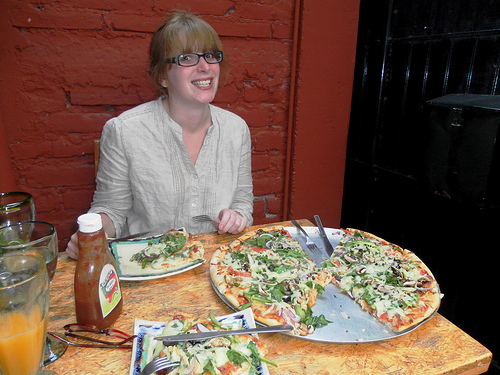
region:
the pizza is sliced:
[217, 227, 429, 369]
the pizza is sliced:
[233, 184, 350, 345]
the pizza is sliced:
[303, 224, 400, 372]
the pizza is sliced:
[266, 207, 383, 344]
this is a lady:
[123, 2, 242, 229]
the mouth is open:
[191, 73, 217, 88]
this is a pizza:
[342, 241, 404, 293]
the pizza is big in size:
[357, 245, 408, 295]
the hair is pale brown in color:
[164, 15, 208, 49]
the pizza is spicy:
[348, 252, 403, 307]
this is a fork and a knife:
[302, 217, 329, 245]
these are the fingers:
[221, 205, 243, 230]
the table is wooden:
[398, 315, 465, 370]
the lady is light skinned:
[186, 100, 206, 124]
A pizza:
[354, 276, 379, 308]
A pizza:
[336, 282, 382, 332]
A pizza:
[246, 214, 284, 293]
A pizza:
[254, 234, 292, 290]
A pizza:
[247, 271, 316, 366]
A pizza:
[199, 189, 299, 374]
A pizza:
[184, 241, 245, 316]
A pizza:
[191, 217, 270, 327]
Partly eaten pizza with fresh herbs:
[211, 213, 444, 347]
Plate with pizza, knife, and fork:
[133, 310, 261, 372]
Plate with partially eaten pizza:
[111, 227, 203, 282]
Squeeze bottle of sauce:
[76, 212, 131, 333]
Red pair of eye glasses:
[43, 321, 136, 350]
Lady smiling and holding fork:
[126, 20, 256, 235]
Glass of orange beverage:
[0, 253, 60, 370]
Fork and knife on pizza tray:
[283, 211, 339, 262]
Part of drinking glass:
[0, 182, 35, 242]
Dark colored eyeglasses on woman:
[157, 48, 227, 70]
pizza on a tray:
[214, 176, 426, 336]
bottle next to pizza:
[78, 218, 136, 353]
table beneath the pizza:
[412, 342, 444, 365]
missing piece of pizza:
[324, 298, 360, 345]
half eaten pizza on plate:
[130, 224, 205, 282]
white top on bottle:
[69, 208, 111, 245]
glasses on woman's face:
[164, 32, 229, 79]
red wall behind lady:
[39, 98, 93, 163]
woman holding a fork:
[193, 201, 244, 243]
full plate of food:
[174, 302, 250, 368]